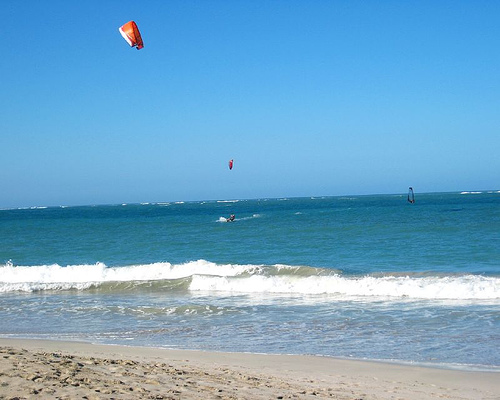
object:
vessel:
[404, 186, 418, 205]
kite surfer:
[223, 211, 242, 226]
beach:
[1, 333, 500, 400]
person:
[403, 182, 418, 207]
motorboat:
[216, 211, 236, 223]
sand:
[0, 342, 290, 400]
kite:
[114, 18, 145, 51]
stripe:
[115, 17, 151, 52]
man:
[221, 210, 242, 228]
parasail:
[227, 159, 236, 171]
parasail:
[111, 17, 148, 55]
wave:
[0, 257, 500, 311]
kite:
[112, 10, 146, 52]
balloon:
[117, 19, 147, 52]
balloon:
[226, 158, 237, 173]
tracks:
[0, 328, 500, 400]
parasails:
[114, 17, 241, 227]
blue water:
[0, 190, 500, 365]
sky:
[0, 0, 499, 210]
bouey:
[405, 185, 416, 203]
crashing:
[0, 250, 500, 316]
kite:
[227, 158, 235, 172]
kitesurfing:
[113, 16, 239, 225]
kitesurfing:
[224, 154, 236, 172]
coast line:
[0, 319, 500, 400]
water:
[0, 186, 498, 374]